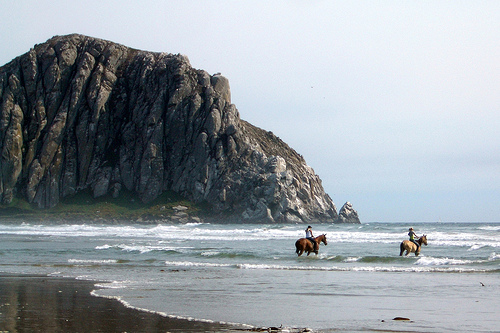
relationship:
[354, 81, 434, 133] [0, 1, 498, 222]
cloud in sky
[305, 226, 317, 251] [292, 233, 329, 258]
man on horse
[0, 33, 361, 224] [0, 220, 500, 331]
rocks next to ocean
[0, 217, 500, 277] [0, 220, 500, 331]
waves crashing in ocean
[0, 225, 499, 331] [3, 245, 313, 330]
waves washing on shore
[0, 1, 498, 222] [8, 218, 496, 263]
sky above ocean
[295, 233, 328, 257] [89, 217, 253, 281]
horse standing in ocean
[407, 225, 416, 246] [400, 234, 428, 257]
rider on brown horse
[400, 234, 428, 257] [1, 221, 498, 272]
brown horse standing in ocean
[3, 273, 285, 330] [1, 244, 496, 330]
sand on beach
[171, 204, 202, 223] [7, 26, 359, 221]
rocks near mountain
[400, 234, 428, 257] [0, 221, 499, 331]
brown horse walking in water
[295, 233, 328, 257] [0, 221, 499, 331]
horse walking in water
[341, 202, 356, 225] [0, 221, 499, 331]
rocks in water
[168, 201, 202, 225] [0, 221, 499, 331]
rocks in water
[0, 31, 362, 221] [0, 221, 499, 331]
rocks in water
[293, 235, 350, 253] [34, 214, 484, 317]
horse in water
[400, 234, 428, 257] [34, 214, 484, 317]
brown horse in water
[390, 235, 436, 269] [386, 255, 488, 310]
brown horse ridden in water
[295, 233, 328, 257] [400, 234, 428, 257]
horse ridden in brown horse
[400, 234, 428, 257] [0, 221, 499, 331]
brown horse ridden in water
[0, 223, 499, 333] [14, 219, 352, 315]
ocean washing onto shore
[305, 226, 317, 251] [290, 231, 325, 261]
man on horse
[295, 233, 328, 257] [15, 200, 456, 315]
horse on beach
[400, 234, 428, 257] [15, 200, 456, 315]
brown horse on beach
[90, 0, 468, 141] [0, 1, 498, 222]
cloud in sky